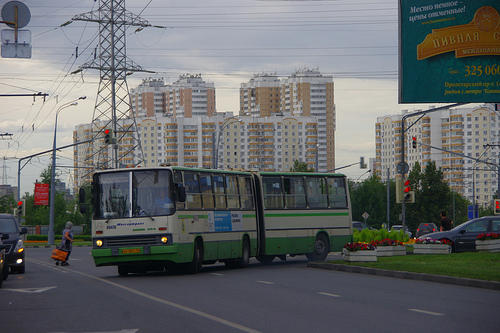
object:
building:
[72, 121, 119, 174]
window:
[298, 131, 303, 136]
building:
[165, 71, 215, 116]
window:
[195, 107, 198, 110]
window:
[467, 131, 471, 135]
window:
[476, 174, 480, 179]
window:
[475, 117, 479, 121]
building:
[440, 103, 500, 210]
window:
[484, 138, 487, 141]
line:
[409, 308, 445, 315]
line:
[209, 315, 249, 330]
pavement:
[0, 302, 68, 330]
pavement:
[472, 302, 497, 327]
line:
[104, 279, 143, 295]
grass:
[416, 258, 463, 268]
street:
[291, 264, 318, 274]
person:
[61, 221, 74, 266]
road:
[270, 306, 297, 327]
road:
[468, 293, 493, 308]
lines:
[319, 292, 340, 298]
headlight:
[160, 236, 167, 243]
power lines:
[62, 68, 64, 71]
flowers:
[344, 242, 359, 252]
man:
[440, 211, 454, 232]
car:
[417, 216, 500, 253]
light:
[161, 237, 168, 243]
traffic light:
[103, 128, 112, 143]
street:
[4, 321, 46, 332]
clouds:
[195, 8, 347, 29]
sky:
[366, 62, 389, 71]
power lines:
[71, 15, 78, 21]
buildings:
[170, 115, 248, 162]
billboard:
[397, 0, 500, 104]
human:
[54, 221, 73, 268]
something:
[51, 249, 68, 261]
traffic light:
[396, 174, 416, 203]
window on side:
[285, 138, 288, 142]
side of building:
[302, 147, 335, 172]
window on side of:
[211, 106, 213, 109]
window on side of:
[276, 106, 279, 109]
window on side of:
[304, 131, 317, 135]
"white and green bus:
[79, 166, 355, 275]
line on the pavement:
[177, 304, 189, 312]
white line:
[95, 277, 116, 286]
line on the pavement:
[62, 266, 75, 271]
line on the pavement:
[151, 296, 174, 306]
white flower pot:
[413, 244, 452, 254]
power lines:
[126, 10, 170, 34]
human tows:
[49, 240, 73, 266]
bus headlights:
[96, 240, 103, 247]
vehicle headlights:
[17, 248, 23, 253]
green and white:
[201, 233, 236, 256]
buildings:
[264, 69, 342, 170]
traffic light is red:
[104, 129, 109, 134]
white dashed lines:
[257, 280, 341, 298]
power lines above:
[44, 56, 88, 99]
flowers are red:
[369, 240, 378, 250]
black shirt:
[441, 217, 452, 230]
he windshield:
[92, 169, 175, 218]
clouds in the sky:
[73, 106, 90, 121]